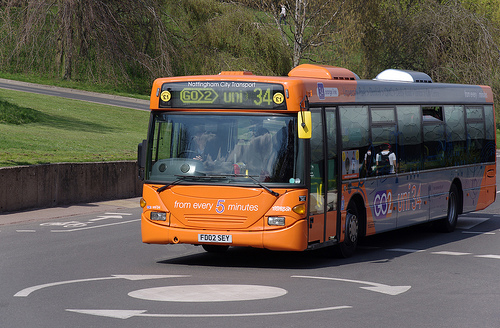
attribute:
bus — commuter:
[146, 65, 425, 280]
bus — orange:
[146, 71, 415, 261]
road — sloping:
[12, 63, 182, 135]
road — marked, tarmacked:
[27, 185, 472, 325]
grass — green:
[2, 90, 168, 211]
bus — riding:
[158, 63, 398, 233]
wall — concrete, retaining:
[26, 160, 152, 209]